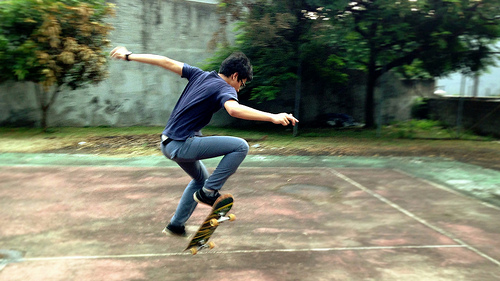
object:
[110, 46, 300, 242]
man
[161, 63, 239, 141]
shirt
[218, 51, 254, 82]
hair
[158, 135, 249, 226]
pants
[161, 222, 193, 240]
shoe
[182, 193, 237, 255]
skateboard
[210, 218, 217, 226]
wheel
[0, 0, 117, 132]
tree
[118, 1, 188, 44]
wall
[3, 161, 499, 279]
concrete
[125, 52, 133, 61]
watch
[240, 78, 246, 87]
glasses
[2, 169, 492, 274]
court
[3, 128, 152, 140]
grass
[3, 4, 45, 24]
leaves